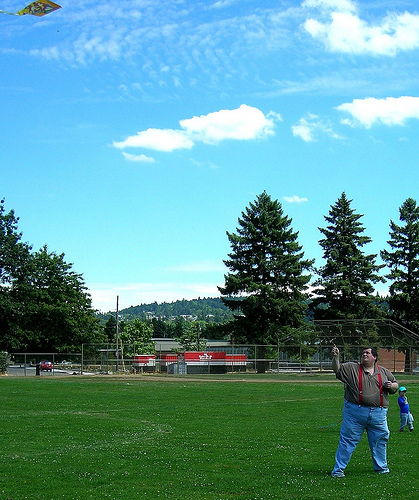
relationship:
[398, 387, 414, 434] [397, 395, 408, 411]
boy wearing shirt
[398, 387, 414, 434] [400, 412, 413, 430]
boy wearing jeans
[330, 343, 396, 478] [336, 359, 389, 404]
man wearing shirt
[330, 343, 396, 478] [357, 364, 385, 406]
man wearing suspenders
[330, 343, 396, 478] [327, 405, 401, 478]
man wearing jeans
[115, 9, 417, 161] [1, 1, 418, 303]
clouds are in sky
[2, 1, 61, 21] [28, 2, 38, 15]
kite with pattern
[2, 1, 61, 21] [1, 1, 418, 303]
kite in sky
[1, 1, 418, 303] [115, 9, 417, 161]
sky with clouds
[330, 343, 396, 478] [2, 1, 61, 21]
guy flying kite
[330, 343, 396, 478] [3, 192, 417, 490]
guy in park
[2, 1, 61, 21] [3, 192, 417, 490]
kite flying in park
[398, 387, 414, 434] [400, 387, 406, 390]
boy has hat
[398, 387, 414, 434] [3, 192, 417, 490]
boy in park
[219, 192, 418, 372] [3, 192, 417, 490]
trees growing near park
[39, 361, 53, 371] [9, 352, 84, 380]
car driving on street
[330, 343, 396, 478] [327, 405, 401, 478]
person wearing jeans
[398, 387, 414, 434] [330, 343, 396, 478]
boy standing behind guy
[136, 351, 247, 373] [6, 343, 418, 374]
buildings are behind fence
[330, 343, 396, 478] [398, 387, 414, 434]
man and boy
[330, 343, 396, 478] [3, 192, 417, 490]
man in park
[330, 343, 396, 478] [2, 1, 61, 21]
man flying kite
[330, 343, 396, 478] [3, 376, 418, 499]
man standing in grass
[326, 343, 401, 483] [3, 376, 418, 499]
boy standing in grass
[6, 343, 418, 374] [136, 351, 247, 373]
fence in front of building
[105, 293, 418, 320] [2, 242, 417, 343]
mountain in background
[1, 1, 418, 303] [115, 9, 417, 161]
sky filled with clouds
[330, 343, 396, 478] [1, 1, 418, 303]
man pointing up to sky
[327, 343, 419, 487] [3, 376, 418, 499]
man and child standing in grass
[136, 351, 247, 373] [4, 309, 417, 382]
building in distance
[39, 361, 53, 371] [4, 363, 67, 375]
car driving down road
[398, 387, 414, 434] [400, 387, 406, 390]
boy wearing hat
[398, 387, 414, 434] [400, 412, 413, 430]
boy wearing pants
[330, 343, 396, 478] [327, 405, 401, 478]
man wearing pants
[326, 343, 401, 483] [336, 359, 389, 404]
boy wearing shirt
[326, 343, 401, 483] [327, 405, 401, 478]
boy wearing jeans